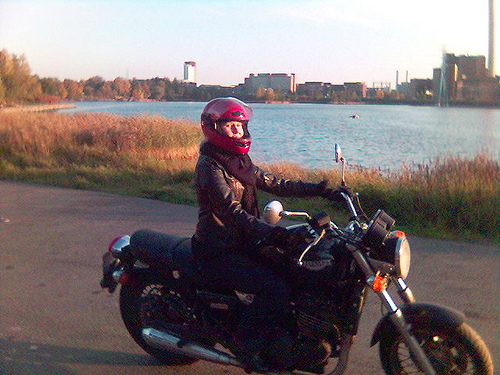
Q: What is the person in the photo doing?
A: Riding a motorcycle.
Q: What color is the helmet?
A: Red.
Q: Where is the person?
A: On the motorcycle.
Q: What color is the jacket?
A: Brown.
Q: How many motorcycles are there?
A: 1.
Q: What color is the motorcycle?
A: Black.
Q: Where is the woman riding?
A: Next to a lake.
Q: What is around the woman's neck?
A: A scarf.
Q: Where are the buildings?
A: Behind the lake.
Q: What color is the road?
A: Gray.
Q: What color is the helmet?
A: Red.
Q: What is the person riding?
A: Motorbike.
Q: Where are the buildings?
A: On the other side of the lake.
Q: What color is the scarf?
A: Black.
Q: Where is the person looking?
A: At the camera.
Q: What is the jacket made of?
A: Leather.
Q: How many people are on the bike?
A: One.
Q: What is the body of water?
A: A lake.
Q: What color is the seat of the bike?
A: Black.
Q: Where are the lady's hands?
A: On the handlebars.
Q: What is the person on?
A: Motorcycle.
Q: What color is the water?
A: Blue.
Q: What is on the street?
A: The bike.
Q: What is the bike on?
A: The street.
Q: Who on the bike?
A: The person.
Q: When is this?
A: Dusk.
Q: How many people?
A: 1.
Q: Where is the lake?
A: Behind the biker.